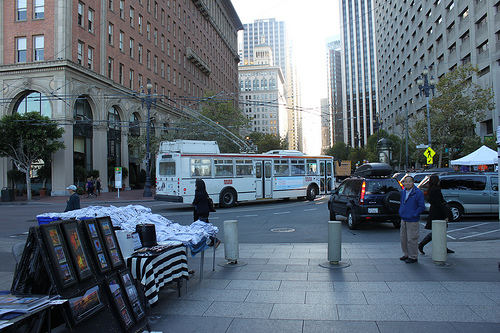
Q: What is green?
A: Trees.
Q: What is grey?
A: Sidewalk.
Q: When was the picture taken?
A: Daytime.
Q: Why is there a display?
A: Items for sale.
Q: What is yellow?
A: Crosswalk sign.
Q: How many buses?
A: One.